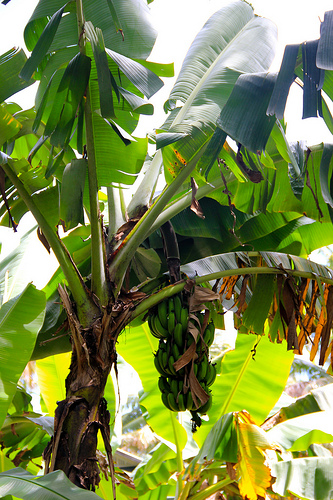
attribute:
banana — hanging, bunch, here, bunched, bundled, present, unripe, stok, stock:
[139, 267, 240, 388]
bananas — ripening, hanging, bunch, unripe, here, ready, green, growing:
[142, 254, 259, 417]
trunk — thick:
[54, 425, 113, 477]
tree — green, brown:
[65, 125, 128, 432]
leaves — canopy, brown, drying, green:
[241, 275, 322, 351]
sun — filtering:
[163, 1, 246, 82]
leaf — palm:
[60, 74, 141, 179]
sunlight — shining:
[174, 19, 240, 86]